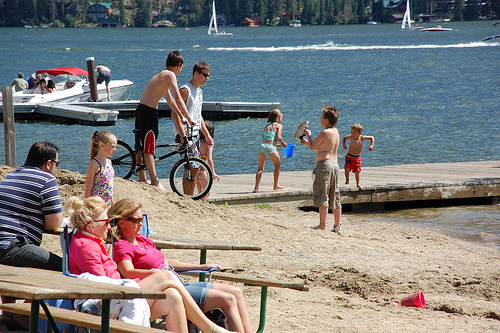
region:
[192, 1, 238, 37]
sailboat with white sails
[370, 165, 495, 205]
wooden beach boardwalk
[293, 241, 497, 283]
tan beach sand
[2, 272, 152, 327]
wooden picnic table and bench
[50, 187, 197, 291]
two women wearing pink shirts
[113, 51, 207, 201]
young man on a bicycle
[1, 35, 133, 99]
people in a white speed boat with a red canopy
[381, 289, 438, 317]
pink plastic bucket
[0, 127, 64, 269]
man in a blue and white striped shirt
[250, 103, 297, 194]
girl in swimsuit holding blue plastic bucket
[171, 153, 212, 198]
Black rubber tire on bicycle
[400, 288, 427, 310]
Pink pail in the sand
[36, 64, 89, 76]
Red top on speed boat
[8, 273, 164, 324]
Wood and metal picnic table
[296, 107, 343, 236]
Boy holding shoe in hand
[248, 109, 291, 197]
Girl holding blue pail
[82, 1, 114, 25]
House with green roof in distance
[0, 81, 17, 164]
Large wooden post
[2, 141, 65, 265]
Guy wearing striped shirt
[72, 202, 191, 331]
Two ladies sitting in chairs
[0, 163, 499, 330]
The beach is sandy.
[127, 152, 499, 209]
The dock is wood.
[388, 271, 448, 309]
The bucket is lying in the sand.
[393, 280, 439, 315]
The bucket is red.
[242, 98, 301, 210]
The girl is carrying a bucket.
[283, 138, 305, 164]
The bucket is blue.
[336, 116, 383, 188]
The boy is wearing swimming trunks.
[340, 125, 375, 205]
The boy is standing on the dock.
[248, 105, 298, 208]
The girl is wearing a bathing suit.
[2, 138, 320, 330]
The man is sitting at the picnic table.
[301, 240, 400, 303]
the beach covered with sand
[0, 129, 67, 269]
a man wearing a blue and white striped shirt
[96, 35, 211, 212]
a boy on a bicycle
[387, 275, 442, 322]
a red bucket in the sand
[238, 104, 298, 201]
a girl holding a blue pail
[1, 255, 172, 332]
a wooden picnic table on the beach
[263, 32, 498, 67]
the wake from the motor boat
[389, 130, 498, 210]
a dock over the water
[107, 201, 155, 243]
a blonde woman wearing sunglasses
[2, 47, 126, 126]
a boat with a red awning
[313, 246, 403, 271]
sand on the beach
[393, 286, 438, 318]
red pail on beach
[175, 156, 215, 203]
front wheel of bicycle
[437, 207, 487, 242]
water nearest the sand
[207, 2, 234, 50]
boat on the water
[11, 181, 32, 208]
stripes on man's shirt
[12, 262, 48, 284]
top of wood bench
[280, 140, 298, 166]
hand holding blue pail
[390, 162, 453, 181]
part of wooden pier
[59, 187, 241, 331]
ladies relaxing on beach